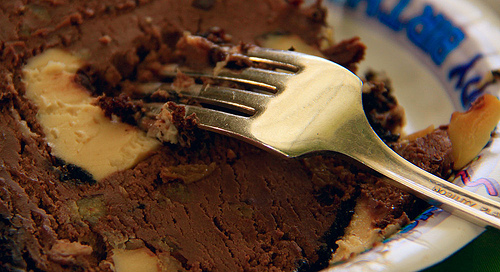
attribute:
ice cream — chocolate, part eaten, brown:
[1, 1, 403, 271]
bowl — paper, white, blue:
[325, 0, 500, 272]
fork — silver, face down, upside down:
[141, 44, 500, 234]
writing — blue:
[348, 0, 466, 66]